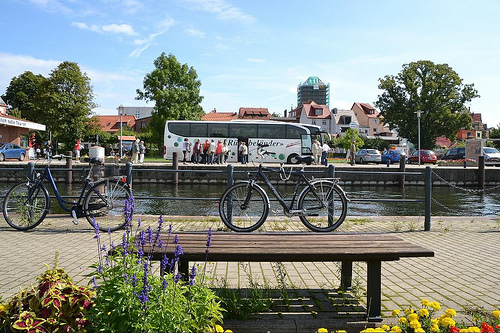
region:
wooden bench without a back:
[100, 223, 431, 324]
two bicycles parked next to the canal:
[2, 138, 348, 233]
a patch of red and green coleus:
[0, 248, 93, 332]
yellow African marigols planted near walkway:
[308, 289, 453, 331]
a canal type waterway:
[8, 165, 497, 213]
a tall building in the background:
[288, 63, 334, 123]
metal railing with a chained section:
[348, 163, 498, 224]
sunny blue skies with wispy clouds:
[0, 2, 300, 54]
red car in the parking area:
[408, 140, 440, 170]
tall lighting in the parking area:
[409, 100, 427, 167]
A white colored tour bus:
[151, 114, 346, 185]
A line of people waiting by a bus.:
[180, 138, 251, 168]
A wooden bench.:
[109, 221, 458, 331]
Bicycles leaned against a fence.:
[8, 149, 367, 236]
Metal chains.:
[427, 167, 498, 217]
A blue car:
[0, 142, 33, 167]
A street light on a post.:
[114, 101, 132, 168]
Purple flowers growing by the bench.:
[91, 184, 213, 331]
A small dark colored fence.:
[3, 161, 440, 246]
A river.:
[3, 174, 498, 223]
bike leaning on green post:
[180, 151, 354, 230]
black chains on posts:
[419, 161, 484, 227]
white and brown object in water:
[85, 136, 115, 186]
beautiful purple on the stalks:
[107, 198, 189, 255]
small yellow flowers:
[402, 304, 459, 326]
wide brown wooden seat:
[99, 204, 442, 269]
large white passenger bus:
[146, 108, 338, 158]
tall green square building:
[285, 67, 334, 99]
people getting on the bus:
[302, 127, 349, 169]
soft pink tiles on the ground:
[443, 241, 463, 301]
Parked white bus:
[156, 115, 327, 160]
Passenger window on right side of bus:
[165, 115, 306, 145]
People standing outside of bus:
[165, 131, 336, 161]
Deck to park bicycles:
[102, 221, 432, 318]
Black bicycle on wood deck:
[212, 156, 348, 236]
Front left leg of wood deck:
[360, 257, 381, 327]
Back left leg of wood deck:
[336, 245, 356, 291]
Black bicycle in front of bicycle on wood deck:
[6, 147, 142, 230]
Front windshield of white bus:
[305, 120, 326, 150]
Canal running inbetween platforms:
[3, 164, 494, 212]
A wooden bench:
[153, 227, 428, 271]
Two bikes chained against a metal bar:
[21, 163, 453, 240]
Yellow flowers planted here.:
[358, 310, 473, 330]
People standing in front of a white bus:
[159, 121, 322, 168]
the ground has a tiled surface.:
[17, 239, 109, 274]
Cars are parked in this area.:
[353, 147, 488, 164]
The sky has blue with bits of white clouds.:
[72, 15, 354, 76]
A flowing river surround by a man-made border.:
[107, 155, 392, 212]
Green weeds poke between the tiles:
[251, 297, 285, 320]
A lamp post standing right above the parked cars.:
[410, 107, 427, 149]